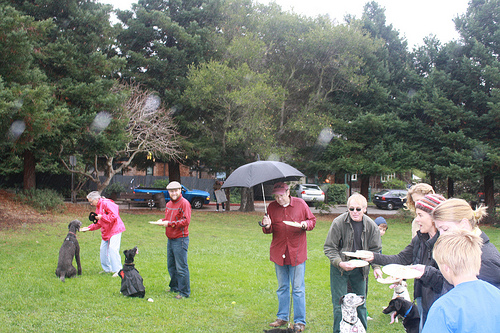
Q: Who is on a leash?
A: The dogs.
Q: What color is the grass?
A: Green.